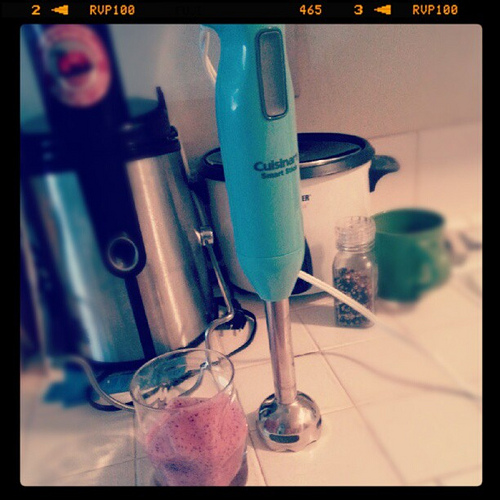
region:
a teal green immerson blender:
[181, 20, 335, 452]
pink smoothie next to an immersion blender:
[80, 256, 353, 488]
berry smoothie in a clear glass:
[98, 336, 261, 485]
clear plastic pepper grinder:
[327, 201, 384, 340]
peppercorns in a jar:
[331, 249, 381, 327]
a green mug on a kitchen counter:
[352, 195, 458, 315]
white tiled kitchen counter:
[304, 327, 494, 467]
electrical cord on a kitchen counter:
[315, 263, 480, 413]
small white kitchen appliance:
[182, 113, 404, 322]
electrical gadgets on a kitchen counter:
[34, 71, 341, 398]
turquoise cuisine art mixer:
[189, 39, 347, 393]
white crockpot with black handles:
[215, 115, 420, 323]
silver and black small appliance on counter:
[26, 83, 280, 413]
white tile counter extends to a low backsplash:
[341, 99, 481, 464]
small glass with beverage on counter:
[101, 332, 280, 465]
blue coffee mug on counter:
[378, 172, 475, 339]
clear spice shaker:
[303, 199, 398, 344]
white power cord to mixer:
[296, 234, 492, 396]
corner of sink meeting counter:
[445, 162, 480, 335]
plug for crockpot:
[195, 261, 280, 339]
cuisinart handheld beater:
[204, 86, 331, 461]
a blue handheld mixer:
[214, 125, 326, 456]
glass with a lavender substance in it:
[99, 323, 259, 483]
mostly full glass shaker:
[328, 207, 390, 347]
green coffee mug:
[366, 178, 456, 315]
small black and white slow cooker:
[160, 117, 407, 301]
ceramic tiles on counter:
[294, 332, 409, 477]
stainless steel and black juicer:
[21, 106, 211, 368]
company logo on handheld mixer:
[236, 131, 316, 194]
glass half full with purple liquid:
[104, 321, 228, 495]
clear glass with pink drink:
[114, 334, 259, 489]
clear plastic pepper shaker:
[328, 219, 385, 338]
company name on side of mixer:
[243, 146, 306, 191]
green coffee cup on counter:
[368, 203, 449, 304]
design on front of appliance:
[32, 25, 133, 135]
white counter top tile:
[360, 410, 472, 472]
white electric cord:
[293, 267, 335, 299]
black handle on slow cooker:
[370, 141, 410, 194]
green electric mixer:
[205, 27, 337, 459]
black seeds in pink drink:
[169, 412, 210, 447]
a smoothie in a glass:
[125, 348, 252, 485]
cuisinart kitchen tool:
[213, 31, 325, 456]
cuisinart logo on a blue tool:
[253, 153, 299, 181]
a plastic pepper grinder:
[332, 216, 377, 326]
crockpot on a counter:
[195, 130, 397, 302]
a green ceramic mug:
[371, 208, 447, 303]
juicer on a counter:
[15, 26, 227, 373]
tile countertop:
[334, 356, 481, 485]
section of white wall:
[298, 29, 478, 126]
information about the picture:
[21, 1, 467, 18]